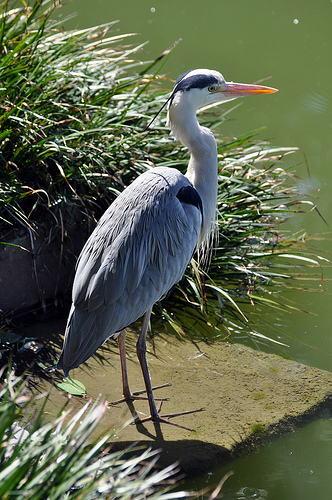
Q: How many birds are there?
A: One.